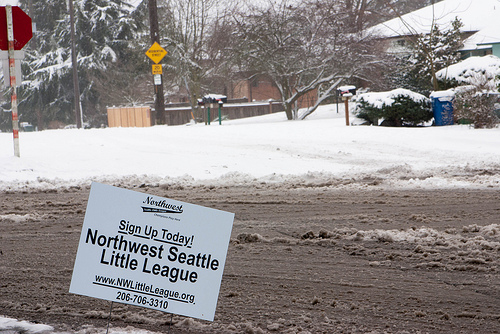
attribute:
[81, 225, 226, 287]
letters — black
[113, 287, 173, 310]
number — phone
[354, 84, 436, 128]
bushes — snowy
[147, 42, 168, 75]
sign — yellow, back, small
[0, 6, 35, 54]
sign — red, stop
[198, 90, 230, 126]
mailboxes — group, line, rowed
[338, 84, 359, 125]
mailbox — snowy, black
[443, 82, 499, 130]
bush — snowy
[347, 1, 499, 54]
house — snowy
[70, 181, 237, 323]
sign — white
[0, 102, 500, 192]
snow — slushy, dirty, slush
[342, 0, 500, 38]
rooftop — snowy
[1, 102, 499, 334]
ground — snowy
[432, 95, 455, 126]
bin — blue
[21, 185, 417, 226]
tracks — car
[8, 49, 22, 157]
pole — attached